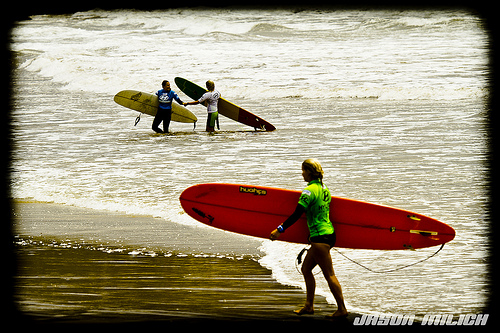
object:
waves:
[11, 10, 489, 319]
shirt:
[197, 90, 220, 115]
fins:
[407, 230, 438, 236]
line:
[177, 197, 454, 236]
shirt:
[152, 89, 185, 111]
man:
[149, 79, 186, 134]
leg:
[316, 250, 347, 309]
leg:
[290, 250, 323, 309]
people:
[149, 79, 186, 134]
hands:
[267, 228, 279, 242]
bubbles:
[9, 10, 488, 101]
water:
[8, 10, 487, 326]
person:
[267, 158, 349, 318]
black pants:
[150, 109, 173, 135]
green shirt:
[297, 179, 337, 238]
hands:
[183, 102, 189, 107]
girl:
[266, 158, 348, 319]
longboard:
[178, 183, 454, 252]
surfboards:
[172, 77, 276, 132]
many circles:
[295, 181, 334, 238]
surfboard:
[112, 90, 197, 124]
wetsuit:
[150, 89, 183, 133]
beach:
[11, 97, 489, 325]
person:
[183, 80, 221, 132]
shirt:
[297, 179, 335, 238]